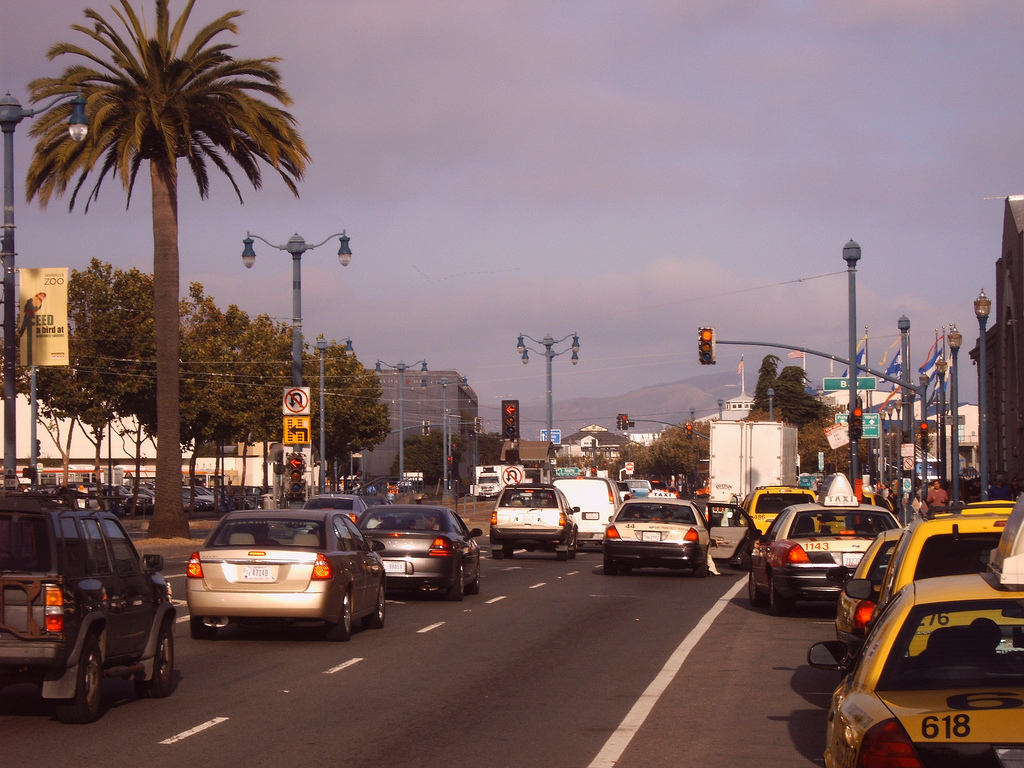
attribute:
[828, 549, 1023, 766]
taxi — cab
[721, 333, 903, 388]
pole — orange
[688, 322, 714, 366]
light — for traffic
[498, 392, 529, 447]
light — red, for traffic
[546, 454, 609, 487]
sign — green, white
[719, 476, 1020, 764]
taxi cabs — yellow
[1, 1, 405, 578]
palm trees — green, large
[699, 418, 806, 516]
truck — large, white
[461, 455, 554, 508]
truck — white, large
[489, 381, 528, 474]
street light — red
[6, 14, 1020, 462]
clouds — dark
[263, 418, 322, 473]
sign — yellow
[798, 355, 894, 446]
street sign — green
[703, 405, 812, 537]
semi truck — white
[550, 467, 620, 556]
van — white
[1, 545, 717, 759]
lane road — dark gray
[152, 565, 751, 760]
lines — white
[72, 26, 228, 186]
tree — largest, palm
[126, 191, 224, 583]
trunk — grey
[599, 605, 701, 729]
line — thick